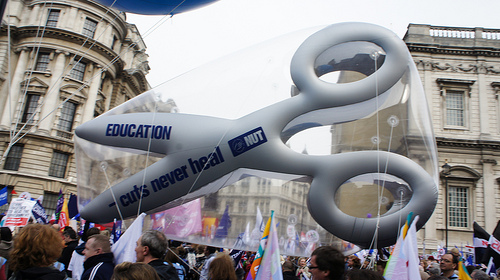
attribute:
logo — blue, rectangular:
[223, 122, 272, 164]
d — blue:
[110, 119, 140, 144]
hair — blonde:
[9, 216, 60, 278]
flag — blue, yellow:
[456, 255, 470, 278]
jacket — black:
[76, 257, 117, 279]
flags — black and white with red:
[466, 207, 496, 278]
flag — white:
[110, 208, 142, 265]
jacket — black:
[74, 254, 129, 278]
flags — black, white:
[474, 222, 499, 272]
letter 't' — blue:
[142, 118, 160, 138]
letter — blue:
[103, 123, 113, 138]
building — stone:
[398, 18, 499, 278]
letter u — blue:
[119, 125, 128, 138]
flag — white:
[250, 210, 290, 279]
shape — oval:
[308, 32, 393, 93]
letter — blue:
[159, 119, 176, 146]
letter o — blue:
[153, 123, 164, 144]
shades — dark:
[305, 260, 320, 271]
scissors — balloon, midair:
[68, 38, 410, 270]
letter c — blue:
[127, 121, 140, 138]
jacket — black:
[77, 251, 116, 278]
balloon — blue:
[98, 1, 223, 18]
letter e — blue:
[104, 124, 116, 136]